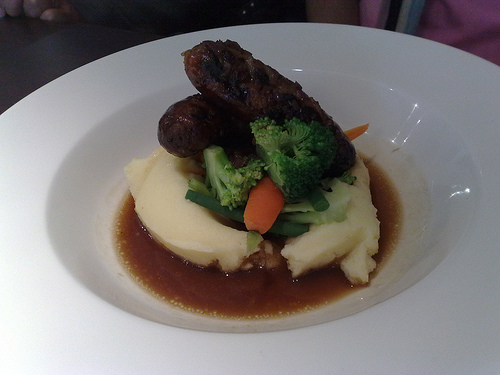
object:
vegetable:
[185, 114, 355, 234]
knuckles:
[2, 0, 62, 18]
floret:
[283, 123, 335, 164]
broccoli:
[247, 116, 346, 198]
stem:
[204, 146, 232, 182]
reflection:
[390, 101, 423, 151]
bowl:
[0, 19, 496, 369]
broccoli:
[252, 117, 340, 193]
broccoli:
[198, 143, 256, 208]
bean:
[305, 186, 328, 213]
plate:
[409, 63, 466, 114]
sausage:
[178, 35, 268, 95]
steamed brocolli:
[250, 122, 338, 191]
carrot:
[243, 178, 279, 231]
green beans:
[282, 221, 298, 233]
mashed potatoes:
[343, 205, 365, 227]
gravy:
[224, 281, 276, 304]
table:
[12, 32, 78, 65]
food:
[122, 36, 383, 285]